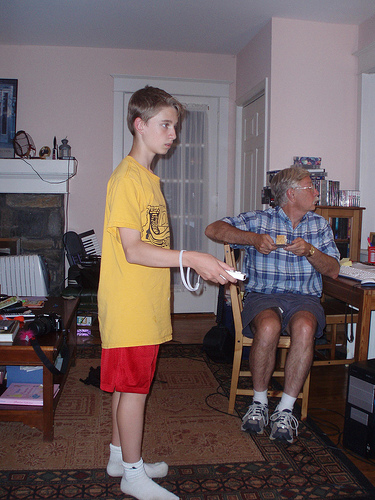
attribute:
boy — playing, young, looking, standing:
[96, 84, 237, 500]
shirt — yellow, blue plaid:
[100, 154, 172, 346]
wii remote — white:
[220, 267, 250, 281]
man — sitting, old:
[204, 162, 338, 440]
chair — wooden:
[220, 243, 311, 421]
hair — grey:
[264, 168, 303, 199]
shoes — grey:
[247, 405, 291, 437]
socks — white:
[252, 390, 297, 409]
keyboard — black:
[61, 226, 97, 262]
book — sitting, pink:
[3, 382, 65, 408]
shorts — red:
[102, 343, 153, 396]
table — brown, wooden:
[324, 263, 375, 359]